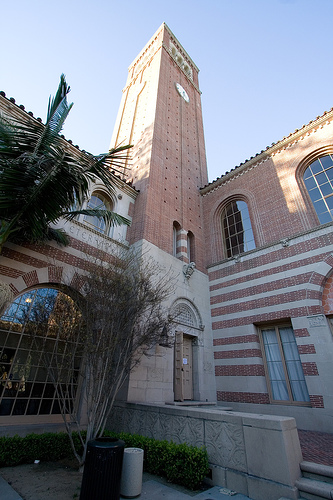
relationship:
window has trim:
[255, 317, 311, 404] [257, 319, 314, 407]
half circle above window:
[213, 187, 252, 214] [219, 197, 255, 261]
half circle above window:
[292, 148, 332, 173] [305, 154, 333, 224]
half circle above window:
[91, 185, 116, 201] [81, 193, 113, 233]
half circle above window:
[7, 268, 102, 315] [2, 285, 87, 417]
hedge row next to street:
[1, 430, 207, 488] [1, 463, 250, 499]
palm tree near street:
[1, 74, 130, 254] [1, 463, 250, 499]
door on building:
[173, 332, 183, 400] [0, 22, 332, 446]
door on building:
[183, 333, 195, 401] [0, 22, 332, 446]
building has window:
[0, 22, 332, 446] [305, 154, 333, 224]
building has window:
[0, 22, 332, 446] [219, 197, 255, 261]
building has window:
[0, 22, 332, 446] [81, 193, 113, 233]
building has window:
[0, 22, 332, 446] [255, 317, 311, 404]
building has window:
[0, 22, 332, 446] [2, 285, 87, 417]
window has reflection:
[2, 285, 87, 417] [1, 291, 85, 391]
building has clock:
[0, 22, 332, 446] [176, 80, 189, 101]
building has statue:
[0, 22, 332, 446] [181, 261, 196, 279]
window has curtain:
[255, 317, 311, 404] [265, 328, 310, 401]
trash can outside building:
[84, 437, 124, 499] [0, 22, 332, 446]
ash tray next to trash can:
[121, 447, 144, 498] [84, 437, 124, 499]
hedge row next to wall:
[1, 430, 207, 488] [102, 398, 303, 498]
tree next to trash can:
[14, 235, 194, 469] [84, 437, 124, 499]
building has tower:
[0, 22, 332, 446] [107, 22, 210, 274]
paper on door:
[183, 358, 190, 366] [183, 333, 195, 401]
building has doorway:
[0, 22, 332, 446] [174, 331, 196, 401]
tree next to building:
[14, 235, 194, 469] [0, 22, 332, 446]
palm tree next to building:
[1, 74, 130, 254] [0, 22, 332, 446]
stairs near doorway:
[295, 461, 332, 498] [174, 331, 196, 401]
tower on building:
[107, 22, 210, 274] [0, 22, 332, 446]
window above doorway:
[173, 222, 177, 257] [174, 331, 196, 401]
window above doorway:
[190, 235, 195, 262] [174, 331, 196, 401]